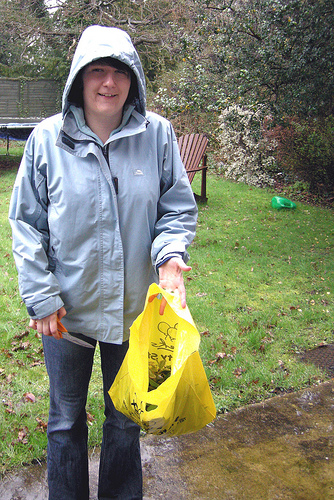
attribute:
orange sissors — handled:
[55, 315, 67, 338]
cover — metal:
[266, 190, 299, 210]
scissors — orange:
[56, 320, 94, 349]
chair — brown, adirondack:
[174, 130, 207, 206]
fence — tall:
[0, 67, 58, 130]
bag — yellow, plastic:
[112, 286, 206, 432]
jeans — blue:
[40, 329, 143, 498]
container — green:
[264, 194, 296, 218]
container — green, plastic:
[263, 193, 300, 213]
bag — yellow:
[106, 281, 218, 437]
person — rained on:
[6, 22, 199, 497]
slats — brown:
[177, 131, 208, 183]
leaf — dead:
[208, 358, 218, 363]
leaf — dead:
[215, 352, 222, 358]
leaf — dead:
[229, 345, 236, 354]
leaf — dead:
[220, 338, 229, 347]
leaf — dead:
[209, 343, 216, 351]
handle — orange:
[54, 319, 66, 336]